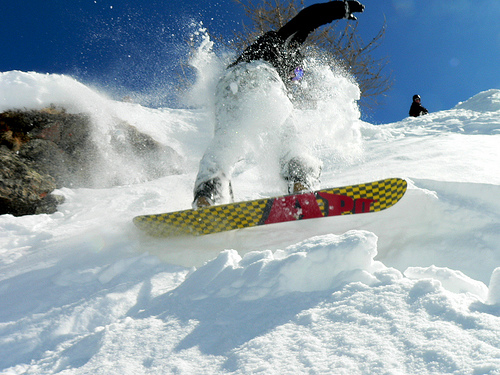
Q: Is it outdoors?
A: Yes, it is outdoors.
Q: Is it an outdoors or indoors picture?
A: It is outdoors.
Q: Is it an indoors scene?
A: No, it is outdoors.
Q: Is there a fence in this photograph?
A: No, there are no fences.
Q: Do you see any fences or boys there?
A: No, there are no fences or boys.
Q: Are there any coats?
A: Yes, there is a coat.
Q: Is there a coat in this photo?
A: Yes, there is a coat.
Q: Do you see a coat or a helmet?
A: Yes, there is a coat.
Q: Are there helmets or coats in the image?
A: Yes, there is a coat.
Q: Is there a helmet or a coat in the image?
A: Yes, there is a coat.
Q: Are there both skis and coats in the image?
A: No, there is a coat but no skis.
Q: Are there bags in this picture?
A: No, there are no bags.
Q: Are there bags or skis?
A: No, there are no bags or skis.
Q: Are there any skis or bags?
A: No, there are no bags or skis.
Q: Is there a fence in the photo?
A: No, there are no fences.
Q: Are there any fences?
A: No, there are no fences.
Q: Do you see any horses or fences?
A: No, there are no fences or horses.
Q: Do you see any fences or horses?
A: No, there are no fences or horses.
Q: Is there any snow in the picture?
A: Yes, there is snow.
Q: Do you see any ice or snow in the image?
A: Yes, there is snow.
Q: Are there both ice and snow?
A: No, there is snow but no ice.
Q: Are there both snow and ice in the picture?
A: No, there is snow but no ice.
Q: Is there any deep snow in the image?
A: Yes, there is deep snow.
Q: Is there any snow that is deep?
A: Yes, there is snow that is deep.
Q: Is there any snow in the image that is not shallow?
A: Yes, there is deep snow.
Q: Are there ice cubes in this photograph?
A: No, there are no ice cubes.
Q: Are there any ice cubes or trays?
A: No, there are no ice cubes or trays.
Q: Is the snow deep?
A: Yes, the snow is deep.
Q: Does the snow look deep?
A: Yes, the snow is deep.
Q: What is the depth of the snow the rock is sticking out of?
A: The snow is deep.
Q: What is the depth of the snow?
A: The snow is deep.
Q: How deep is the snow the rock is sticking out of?
A: The snow is deep.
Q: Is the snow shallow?
A: No, the snow is deep.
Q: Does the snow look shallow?
A: No, the snow is deep.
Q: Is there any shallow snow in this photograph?
A: No, there is snow but it is deep.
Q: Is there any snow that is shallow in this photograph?
A: No, there is snow but it is deep.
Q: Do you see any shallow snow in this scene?
A: No, there is snow but it is deep.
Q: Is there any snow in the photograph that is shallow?
A: No, there is snow but it is deep.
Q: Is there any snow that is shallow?
A: No, there is snow but it is deep.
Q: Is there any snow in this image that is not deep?
A: No, there is snow but it is deep.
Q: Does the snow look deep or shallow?
A: The snow is deep.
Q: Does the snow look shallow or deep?
A: The snow is deep.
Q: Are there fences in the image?
A: No, there are no fences.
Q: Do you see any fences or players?
A: No, there are no fences or players.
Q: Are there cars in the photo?
A: No, there are no cars.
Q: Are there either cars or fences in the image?
A: No, there are no cars or fences.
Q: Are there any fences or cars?
A: No, there are no cars or fences.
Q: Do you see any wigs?
A: No, there are no wigs.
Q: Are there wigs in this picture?
A: No, there are no wigs.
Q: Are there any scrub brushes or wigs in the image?
A: No, there are no wigs or scrub brushes.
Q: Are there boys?
A: No, there are no boys.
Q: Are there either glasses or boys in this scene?
A: No, there are no boys or glasses.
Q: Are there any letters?
A: Yes, there are letters.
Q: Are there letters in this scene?
A: Yes, there are letters.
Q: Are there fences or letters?
A: Yes, there are letters.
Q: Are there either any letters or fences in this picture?
A: Yes, there are letters.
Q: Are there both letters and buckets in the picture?
A: No, there are letters but no buckets.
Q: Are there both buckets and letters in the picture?
A: No, there are letters but no buckets.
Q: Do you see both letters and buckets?
A: No, there are letters but no buckets.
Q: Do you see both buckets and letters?
A: No, there are letters but no buckets.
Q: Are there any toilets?
A: No, there are no toilets.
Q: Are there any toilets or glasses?
A: No, there are no toilets or glasses.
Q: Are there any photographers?
A: No, there are no photographers.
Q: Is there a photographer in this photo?
A: No, there are no photographers.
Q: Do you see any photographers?
A: No, there are no photographers.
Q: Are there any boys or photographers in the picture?
A: No, there are no photographers or boys.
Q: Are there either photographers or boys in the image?
A: No, there are no photographers or boys.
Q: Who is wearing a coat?
A: The man is wearing a coat.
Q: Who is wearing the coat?
A: The man is wearing a coat.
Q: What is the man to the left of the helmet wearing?
A: The man is wearing a coat.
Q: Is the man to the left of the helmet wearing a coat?
A: Yes, the man is wearing a coat.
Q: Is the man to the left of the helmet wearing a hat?
A: No, the man is wearing a coat.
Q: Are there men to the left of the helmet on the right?
A: Yes, there is a man to the left of the helmet.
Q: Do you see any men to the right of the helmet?
A: No, the man is to the left of the helmet.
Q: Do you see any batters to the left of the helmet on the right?
A: No, there is a man to the left of the helmet.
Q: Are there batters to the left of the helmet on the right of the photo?
A: No, there is a man to the left of the helmet.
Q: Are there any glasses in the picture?
A: No, there are no glasses.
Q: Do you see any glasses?
A: No, there are no glasses.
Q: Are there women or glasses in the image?
A: No, there are no glasses or women.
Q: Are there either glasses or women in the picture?
A: No, there are no glasses or women.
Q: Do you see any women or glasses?
A: No, there are no glasses or women.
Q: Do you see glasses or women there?
A: No, there are no glasses or women.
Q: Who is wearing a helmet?
A: The man is wearing a helmet.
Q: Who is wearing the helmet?
A: The man is wearing a helmet.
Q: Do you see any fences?
A: No, there are no fences.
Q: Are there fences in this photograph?
A: No, there are no fences.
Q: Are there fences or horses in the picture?
A: No, there are no fences or horses.